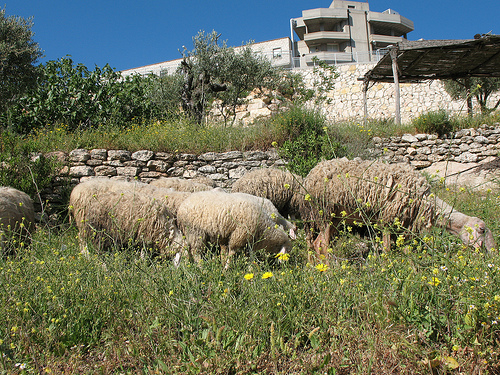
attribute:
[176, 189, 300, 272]
sheep — grazing, wooly, five, a flock, eating, white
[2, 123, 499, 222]
wall — stone, short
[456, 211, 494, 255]
head — shaved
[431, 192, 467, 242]
neck — shaved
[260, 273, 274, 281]
flowers — yellow, growing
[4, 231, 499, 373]
grass — tall, growing, green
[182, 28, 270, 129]
trees — green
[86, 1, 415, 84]
building — grey, tall, gray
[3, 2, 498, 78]
sky — blue, clear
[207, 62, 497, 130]
wall — large, stone, tall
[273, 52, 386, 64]
fence — metal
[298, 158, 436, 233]
wool — long, brown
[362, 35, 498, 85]
roof — large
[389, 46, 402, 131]
supports — wooden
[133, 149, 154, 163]
rocks — gray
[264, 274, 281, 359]
plants — green